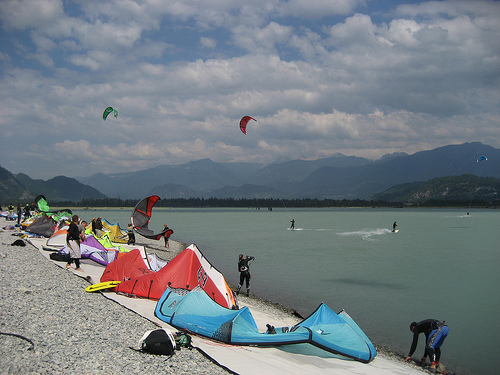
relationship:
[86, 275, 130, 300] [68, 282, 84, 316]
surfboard on ground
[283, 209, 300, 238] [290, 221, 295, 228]
person wearing a wetsuit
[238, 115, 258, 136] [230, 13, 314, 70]
kite in sky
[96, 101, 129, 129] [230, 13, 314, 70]
green kite in sky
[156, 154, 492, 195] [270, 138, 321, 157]
mountains in background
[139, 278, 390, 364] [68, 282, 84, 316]
kite on ground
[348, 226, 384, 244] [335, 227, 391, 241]
white splashes of white splashes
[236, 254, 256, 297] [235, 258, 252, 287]
girl in a black suit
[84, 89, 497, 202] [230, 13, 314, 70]
kites in sky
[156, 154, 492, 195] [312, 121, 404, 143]
mountains in distance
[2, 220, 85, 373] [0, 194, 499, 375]
beach with beach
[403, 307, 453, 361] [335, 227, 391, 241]
guy standing near white splashes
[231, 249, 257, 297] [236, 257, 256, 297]
girl wearing a black suit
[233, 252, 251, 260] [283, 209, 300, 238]
head of a person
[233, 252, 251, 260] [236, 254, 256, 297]
head of a girl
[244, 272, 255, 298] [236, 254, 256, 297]
leg of a girl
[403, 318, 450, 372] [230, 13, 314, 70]
guy in sky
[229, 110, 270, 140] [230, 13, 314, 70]
red kite in sky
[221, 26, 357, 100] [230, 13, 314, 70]
clouds in sky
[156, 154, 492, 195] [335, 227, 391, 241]
mountains behind white splashes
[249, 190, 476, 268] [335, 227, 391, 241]
people in white splashes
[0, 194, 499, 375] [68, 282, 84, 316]
beach on ground